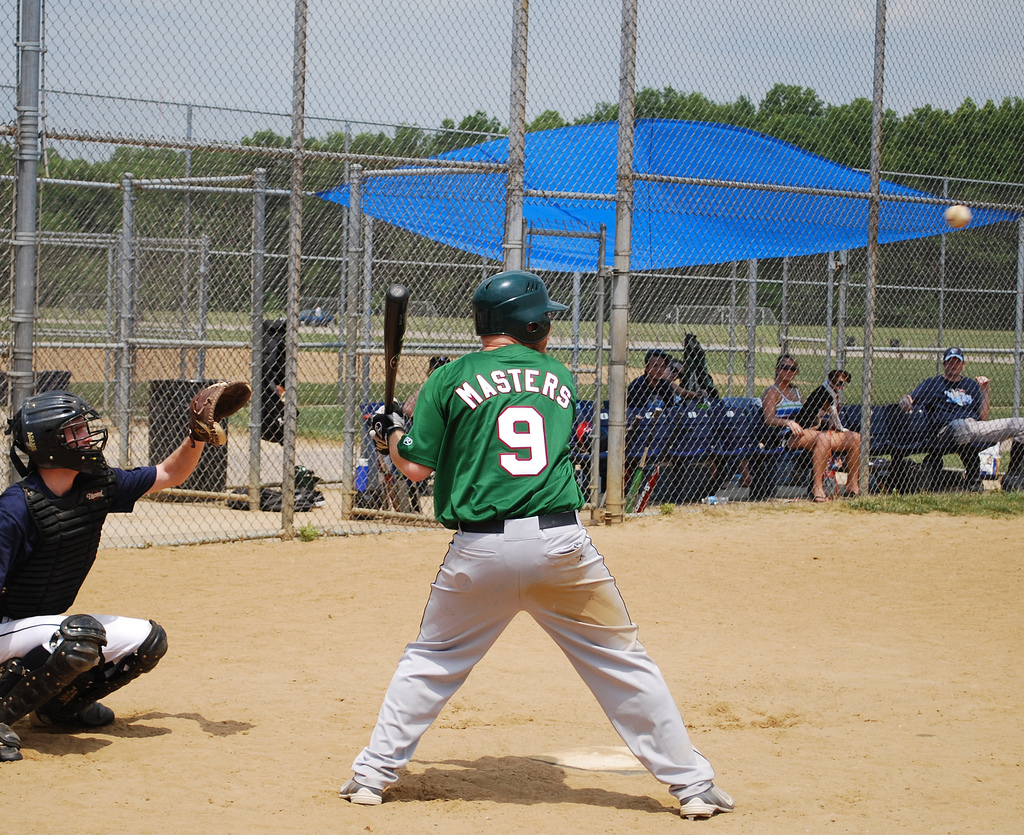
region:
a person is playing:
[357, 251, 738, 817]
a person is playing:
[3, 395, 253, 728]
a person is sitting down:
[609, 335, 673, 399]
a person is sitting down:
[676, 354, 716, 403]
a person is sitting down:
[906, 336, 1017, 480]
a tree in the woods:
[884, 92, 954, 334]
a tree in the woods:
[237, 130, 302, 299]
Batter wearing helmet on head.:
[458, 265, 557, 327]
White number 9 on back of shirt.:
[490, 402, 552, 494]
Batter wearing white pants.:
[417, 528, 693, 800]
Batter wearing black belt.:
[448, 506, 597, 538]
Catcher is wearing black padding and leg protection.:
[34, 483, 159, 719]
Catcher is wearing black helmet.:
[29, 392, 110, 479]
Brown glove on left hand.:
[174, 367, 285, 456]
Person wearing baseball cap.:
[932, 339, 967, 362]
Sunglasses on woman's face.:
[771, 361, 801, 380]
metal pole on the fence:
[848, 2, 899, 486]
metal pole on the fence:
[599, 0, 641, 520]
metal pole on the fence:
[503, 0, 535, 273]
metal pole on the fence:
[334, 157, 364, 512]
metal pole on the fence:
[275, 0, 311, 531]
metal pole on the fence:
[242, 166, 265, 506]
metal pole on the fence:
[114, 163, 140, 467]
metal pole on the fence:
[10, 0, 42, 396]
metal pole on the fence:
[185, 226, 206, 376]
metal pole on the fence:
[741, 255, 761, 396]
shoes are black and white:
[674, 774, 745, 832]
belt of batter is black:
[451, 491, 600, 534]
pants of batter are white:
[340, 506, 752, 811]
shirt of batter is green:
[413, 317, 603, 527]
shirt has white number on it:
[498, 411, 555, 485]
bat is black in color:
[362, 265, 423, 440]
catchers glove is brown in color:
[143, 367, 239, 453]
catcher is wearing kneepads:
[26, 594, 109, 683]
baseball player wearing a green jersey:
[396, 348, 581, 517]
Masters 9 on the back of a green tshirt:
[457, 349, 589, 490]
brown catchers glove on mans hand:
[187, 375, 278, 481]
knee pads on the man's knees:
[52, 609, 183, 690]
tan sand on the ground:
[850, 679, 974, 797]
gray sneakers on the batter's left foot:
[297, 741, 375, 832]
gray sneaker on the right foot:
[666, 766, 744, 815]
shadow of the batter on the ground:
[433, 742, 633, 826]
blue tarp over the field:
[261, 81, 1009, 285]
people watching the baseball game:
[606, 313, 999, 514]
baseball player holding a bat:
[355, 272, 730, 808]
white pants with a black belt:
[354, 512, 710, 794]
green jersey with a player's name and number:
[411, 344, 588, 507]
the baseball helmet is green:
[479, 275, 569, 334]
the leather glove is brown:
[188, 380, 255, 442]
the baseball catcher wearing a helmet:
[13, 397, 113, 489]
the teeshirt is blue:
[7, 465, 160, 608]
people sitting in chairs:
[626, 342, 1016, 473]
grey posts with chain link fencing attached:
[0, 4, 1019, 488]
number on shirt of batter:
[495, 405, 546, 475]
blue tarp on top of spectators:
[317, 122, 1021, 273]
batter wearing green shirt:
[399, 341, 581, 526]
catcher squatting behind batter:
[0, 380, 251, 762]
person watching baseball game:
[760, 346, 874, 502]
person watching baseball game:
[624, 339, 684, 409]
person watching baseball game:
[897, 346, 1021, 487]